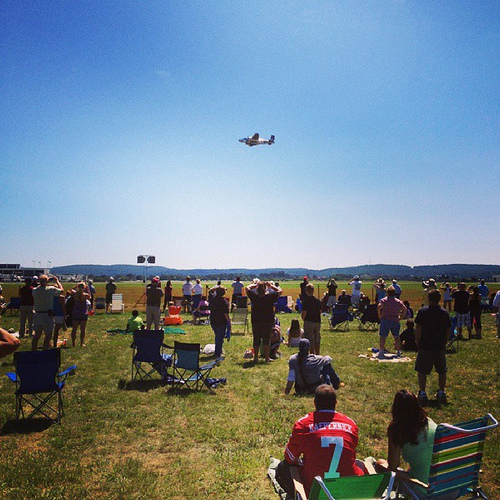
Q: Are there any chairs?
A: Yes, there is a chair.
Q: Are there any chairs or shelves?
A: Yes, there is a chair.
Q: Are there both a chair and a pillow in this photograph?
A: No, there is a chair but no pillows.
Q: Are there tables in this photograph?
A: No, there are no tables.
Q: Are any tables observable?
A: No, there are no tables.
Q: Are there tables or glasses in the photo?
A: No, there are no tables or glasses.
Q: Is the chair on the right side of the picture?
A: No, the chair is on the left of the image.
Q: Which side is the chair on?
A: The chair is on the left of the image.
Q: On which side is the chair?
A: The chair is on the left of the image.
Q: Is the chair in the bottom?
A: Yes, the chair is in the bottom of the image.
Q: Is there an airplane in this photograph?
A: Yes, there is an airplane.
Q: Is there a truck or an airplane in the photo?
A: Yes, there is an airplane.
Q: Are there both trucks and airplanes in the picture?
A: No, there is an airplane but no trucks.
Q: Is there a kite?
A: No, there are no kites.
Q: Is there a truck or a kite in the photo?
A: No, there are no kites or trucks.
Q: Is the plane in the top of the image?
A: Yes, the plane is in the top of the image.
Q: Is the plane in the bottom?
A: No, the plane is in the top of the image.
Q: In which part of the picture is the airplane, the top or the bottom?
A: The airplane is in the top of the image.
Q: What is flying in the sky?
A: The airplane is flying in the sky.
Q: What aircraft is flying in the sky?
A: The aircraft is an airplane.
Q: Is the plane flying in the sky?
A: Yes, the plane is flying in the sky.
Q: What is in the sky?
A: The airplane is in the sky.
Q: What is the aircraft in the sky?
A: The aircraft is an airplane.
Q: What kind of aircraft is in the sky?
A: The aircraft is an airplane.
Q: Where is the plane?
A: The plane is in the sky.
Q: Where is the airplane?
A: The plane is in the sky.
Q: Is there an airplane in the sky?
A: Yes, there is an airplane in the sky.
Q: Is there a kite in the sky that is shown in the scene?
A: No, there is an airplane in the sky.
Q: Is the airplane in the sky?
A: Yes, the airplane is in the sky.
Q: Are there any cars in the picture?
A: No, there are no cars.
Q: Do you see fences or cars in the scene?
A: No, there are no cars or fences.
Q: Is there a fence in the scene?
A: No, there are no fences.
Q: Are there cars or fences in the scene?
A: No, there are no fences or cars.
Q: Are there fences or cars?
A: No, there are no fences or cars.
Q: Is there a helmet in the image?
A: No, there are no helmets.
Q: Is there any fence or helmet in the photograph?
A: No, there are no helmets or fences.